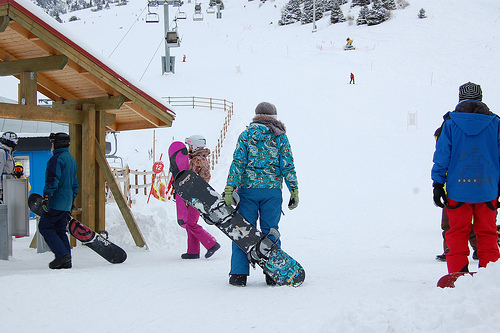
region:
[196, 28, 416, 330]
snowy ski slope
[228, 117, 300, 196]
varied blue colored parka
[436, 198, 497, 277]
red snow pants with suspenders hanging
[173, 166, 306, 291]
carrying a snow board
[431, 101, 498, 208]
blue parka with hood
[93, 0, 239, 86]
a chairlift to top of ski trail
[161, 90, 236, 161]
wood rail fencing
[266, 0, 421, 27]
cluster of snow covered pines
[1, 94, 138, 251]
wood support beams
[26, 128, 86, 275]
teal and black outfit on snowboarder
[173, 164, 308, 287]
A black and blue snowboard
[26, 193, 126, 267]
A red and black snowboard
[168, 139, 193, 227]
A pink and black snowbaord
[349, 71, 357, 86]
A man in red snowboarding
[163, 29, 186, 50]
A seat on the elevator to the top of the ramp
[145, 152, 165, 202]
A sign with the number 12 on it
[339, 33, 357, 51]
A man in yellow skiing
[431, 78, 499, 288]
A man in blue and red watching the slope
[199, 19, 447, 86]
Trail makers for the slope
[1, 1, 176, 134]
A wooden roof over a break area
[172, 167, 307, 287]
A black and blue board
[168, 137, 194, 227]
A pink and black board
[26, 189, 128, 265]
A black and red board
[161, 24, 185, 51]
A car going up the ski lift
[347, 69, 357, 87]
a man in a red jacket skiing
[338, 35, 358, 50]
A man in a yellow jacket skiing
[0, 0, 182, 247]
A wooden shelter with a roof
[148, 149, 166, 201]
An orange sign with numbers on it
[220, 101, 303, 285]
A woman watching the slopes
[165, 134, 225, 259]
A woman heading towards the shelter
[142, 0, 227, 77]
ski lift baskets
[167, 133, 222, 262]
woman with pink pants and matching snowboard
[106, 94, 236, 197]
wooden fencing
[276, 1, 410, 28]
group of fir trees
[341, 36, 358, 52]
snowboarder on a hill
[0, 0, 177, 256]
wooden platform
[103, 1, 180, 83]
guy wires holding ski baskets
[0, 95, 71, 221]
blue building with metal roof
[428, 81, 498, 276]
man wearing blue hooded jacket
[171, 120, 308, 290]
snowboard and jacket with matching designs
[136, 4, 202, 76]
Ski lift pole and cars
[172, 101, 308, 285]
Person holding blue snowboard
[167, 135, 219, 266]
Person carrying pink snow board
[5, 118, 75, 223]
Blue building with grey roof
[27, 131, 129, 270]
Person carrying black and red snow board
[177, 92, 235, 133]
Brown fence in white snow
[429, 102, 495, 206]
Person wearing blue jacket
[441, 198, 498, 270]
Person wearing red snow pants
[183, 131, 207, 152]
Person wearing white helmet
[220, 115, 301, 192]
Person wearing blue pattern jacket